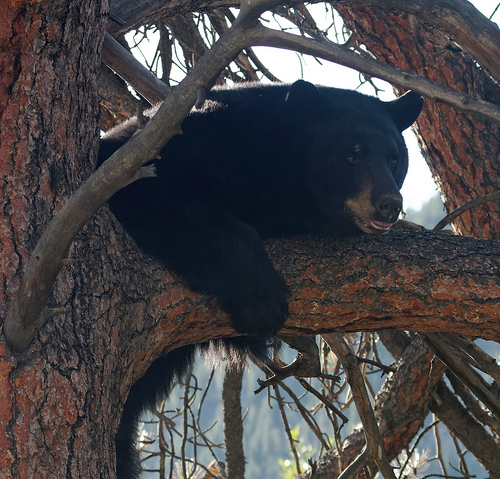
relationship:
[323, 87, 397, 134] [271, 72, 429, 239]
top on head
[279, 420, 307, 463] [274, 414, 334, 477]
leaves on plant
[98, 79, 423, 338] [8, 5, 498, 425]
bear on tree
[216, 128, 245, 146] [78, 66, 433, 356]
fur on bear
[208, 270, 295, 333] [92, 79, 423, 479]
bearpaw on bear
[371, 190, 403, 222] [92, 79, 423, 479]
nose on bear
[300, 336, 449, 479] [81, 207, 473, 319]
branch under tree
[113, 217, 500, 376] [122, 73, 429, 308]
branch under bear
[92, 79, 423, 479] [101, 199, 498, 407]
bear resting on branch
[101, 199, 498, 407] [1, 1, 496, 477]
branch on tree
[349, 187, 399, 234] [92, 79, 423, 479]
mouth on bear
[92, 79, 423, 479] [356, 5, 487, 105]
bear in tree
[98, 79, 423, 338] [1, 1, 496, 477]
bear in tree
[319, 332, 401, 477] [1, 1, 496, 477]
branch of tree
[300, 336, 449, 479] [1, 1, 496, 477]
branch of tree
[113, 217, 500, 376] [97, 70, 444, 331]
branch under bear